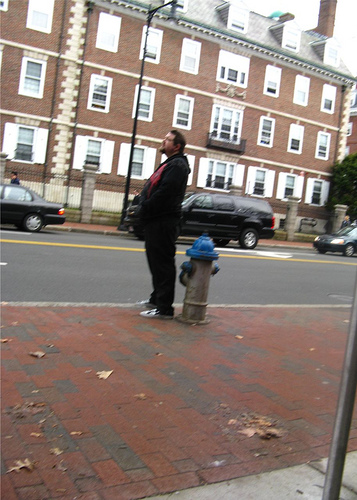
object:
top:
[185, 229, 220, 261]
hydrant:
[175, 232, 221, 327]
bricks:
[95, 388, 133, 414]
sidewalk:
[0, 299, 168, 499]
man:
[133, 129, 191, 321]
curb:
[0, 299, 137, 309]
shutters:
[1, 120, 51, 165]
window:
[17, 50, 47, 100]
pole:
[321, 277, 357, 500]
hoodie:
[133, 152, 192, 235]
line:
[54, 241, 138, 251]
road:
[0, 225, 357, 305]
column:
[79, 159, 100, 225]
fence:
[92, 176, 146, 214]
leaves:
[236, 415, 282, 440]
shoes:
[139, 308, 175, 320]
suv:
[123, 190, 276, 250]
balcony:
[205, 131, 247, 156]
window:
[208, 98, 244, 145]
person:
[10, 170, 20, 184]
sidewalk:
[60, 218, 126, 232]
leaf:
[95, 368, 113, 380]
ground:
[115, 344, 229, 390]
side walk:
[143, 303, 357, 499]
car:
[0, 183, 67, 232]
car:
[312, 222, 357, 257]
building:
[0, 0, 357, 243]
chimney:
[314, 0, 337, 40]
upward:
[158, 129, 188, 158]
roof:
[300, 28, 357, 86]